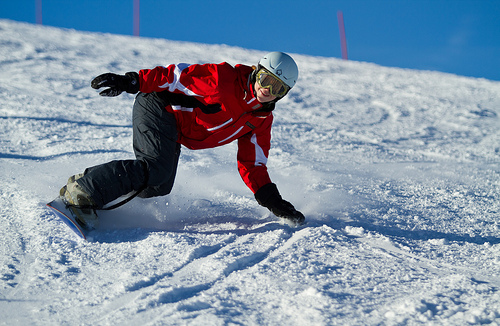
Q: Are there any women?
A: Yes, there is a woman.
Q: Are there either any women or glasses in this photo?
A: Yes, there is a woman.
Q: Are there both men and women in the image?
A: No, there is a woman but no men.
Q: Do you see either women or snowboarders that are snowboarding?
A: Yes, the woman is snowboarding.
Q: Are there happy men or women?
A: Yes, there is a happy woman.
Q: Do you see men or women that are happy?
A: Yes, the woman is happy.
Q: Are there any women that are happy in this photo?
A: Yes, there is a happy woman.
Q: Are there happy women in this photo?
A: Yes, there is a happy woman.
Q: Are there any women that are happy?
A: Yes, there is a woman that is happy.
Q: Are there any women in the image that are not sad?
A: Yes, there is a happy woman.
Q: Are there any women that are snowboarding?
A: Yes, there is a woman that is snowboarding.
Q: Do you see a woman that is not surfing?
A: Yes, there is a woman that is snowboarding .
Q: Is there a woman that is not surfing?
A: Yes, there is a woman that is snowboarding.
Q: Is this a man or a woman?
A: This is a woman.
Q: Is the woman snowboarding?
A: Yes, the woman is snowboarding.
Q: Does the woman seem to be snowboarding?
A: Yes, the woman is snowboarding.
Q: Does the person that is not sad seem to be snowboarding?
A: Yes, the woman is snowboarding.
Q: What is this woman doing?
A: The woman is snowboarding.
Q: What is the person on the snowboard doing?
A: The woman is snowboarding.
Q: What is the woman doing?
A: The woman is snowboarding.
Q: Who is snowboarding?
A: The woman is snowboarding.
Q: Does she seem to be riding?
A: No, the woman is snowboarding.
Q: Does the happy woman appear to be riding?
A: No, the woman is snowboarding.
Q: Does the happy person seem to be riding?
A: No, the woman is snowboarding.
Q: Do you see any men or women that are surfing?
A: No, there is a woman but she is snowboarding.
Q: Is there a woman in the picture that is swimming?
A: No, there is a woman but she is snowboarding.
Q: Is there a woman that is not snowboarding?
A: No, there is a woman but she is snowboarding.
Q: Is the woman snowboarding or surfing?
A: The woman is snowboarding.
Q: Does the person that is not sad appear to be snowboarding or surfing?
A: The woman is snowboarding.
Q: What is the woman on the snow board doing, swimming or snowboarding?
A: The woman is snowboarding.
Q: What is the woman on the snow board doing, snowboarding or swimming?
A: The woman is snowboarding.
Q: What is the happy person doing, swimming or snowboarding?
A: The woman is snowboarding.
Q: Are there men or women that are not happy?
A: No, there is a woman but she is happy.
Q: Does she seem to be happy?
A: Yes, the woman is happy.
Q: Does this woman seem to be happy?
A: Yes, the woman is happy.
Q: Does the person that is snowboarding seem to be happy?
A: Yes, the woman is happy.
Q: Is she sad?
A: No, the woman is happy.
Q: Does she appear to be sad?
A: No, the woman is happy.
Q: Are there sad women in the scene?
A: No, there is a woman but she is happy.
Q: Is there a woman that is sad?
A: No, there is a woman but she is happy.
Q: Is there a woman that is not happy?
A: No, there is a woman but she is happy.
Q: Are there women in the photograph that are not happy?
A: No, there is a woman but she is happy.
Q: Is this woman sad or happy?
A: The woman is happy.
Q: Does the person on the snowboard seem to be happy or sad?
A: The woman is happy.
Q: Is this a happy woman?
A: Yes, this is a happy woman.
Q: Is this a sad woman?
A: No, this is a happy woman.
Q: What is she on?
A: The woman is on the snowboard.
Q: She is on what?
A: The woman is on the snowboard.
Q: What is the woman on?
A: The woman is on the snowboard.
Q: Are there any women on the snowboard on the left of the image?
A: Yes, there is a woman on the snowboard.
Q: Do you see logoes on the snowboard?
A: No, there is a woman on the snowboard.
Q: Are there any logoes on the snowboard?
A: No, there is a woman on the snowboard.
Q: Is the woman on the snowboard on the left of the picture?
A: Yes, the woman is on the snowboard.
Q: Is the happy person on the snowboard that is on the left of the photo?
A: Yes, the woman is on the snowboard.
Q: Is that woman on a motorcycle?
A: No, the woman is on the snowboard.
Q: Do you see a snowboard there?
A: Yes, there is a snowboard.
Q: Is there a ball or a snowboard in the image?
A: Yes, there is a snowboard.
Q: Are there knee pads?
A: No, there are no knee pads.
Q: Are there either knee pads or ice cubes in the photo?
A: No, there are no knee pads or ice cubes.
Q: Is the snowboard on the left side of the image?
A: Yes, the snowboard is on the left of the image.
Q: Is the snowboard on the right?
A: No, the snowboard is on the left of the image.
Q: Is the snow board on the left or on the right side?
A: The snow board is on the left of the image.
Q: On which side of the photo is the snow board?
A: The snow board is on the left of the image.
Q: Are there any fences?
A: No, there are no fences.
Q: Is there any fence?
A: No, there are no fences.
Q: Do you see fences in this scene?
A: No, there are no fences.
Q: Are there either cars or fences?
A: No, there are no fences or cars.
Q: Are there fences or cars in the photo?
A: No, there are no fences or cars.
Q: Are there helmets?
A: Yes, there is a helmet.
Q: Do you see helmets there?
A: Yes, there is a helmet.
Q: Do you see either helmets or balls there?
A: Yes, there is a helmet.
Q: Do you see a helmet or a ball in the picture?
A: Yes, there is a helmet.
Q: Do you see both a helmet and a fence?
A: No, there is a helmet but no fences.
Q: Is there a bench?
A: No, there are no benches.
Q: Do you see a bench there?
A: No, there are no benches.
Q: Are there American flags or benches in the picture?
A: No, there are no benches or American flags.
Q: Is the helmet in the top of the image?
A: Yes, the helmet is in the top of the image.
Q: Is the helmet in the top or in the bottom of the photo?
A: The helmet is in the top of the image.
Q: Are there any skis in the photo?
A: No, there are no skis.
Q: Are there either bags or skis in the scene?
A: No, there are no skis or bags.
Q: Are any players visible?
A: No, there are no players.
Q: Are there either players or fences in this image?
A: No, there are no players or fences.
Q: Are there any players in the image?
A: No, there are no players.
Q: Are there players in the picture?
A: No, there are no players.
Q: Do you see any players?
A: No, there are no players.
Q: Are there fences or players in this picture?
A: No, there are no players or fences.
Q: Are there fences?
A: No, there are no fences.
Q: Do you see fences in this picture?
A: No, there are no fences.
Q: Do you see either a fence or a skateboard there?
A: No, there are no fences or skateboards.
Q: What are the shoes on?
A: The shoes are on the snowboard.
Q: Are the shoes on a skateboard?
A: No, the shoes are on the snowboard.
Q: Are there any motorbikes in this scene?
A: No, there are no motorbikes.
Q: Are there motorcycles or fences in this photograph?
A: No, there are no motorcycles or fences.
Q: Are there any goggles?
A: Yes, there are goggles.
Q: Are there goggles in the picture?
A: Yes, there are goggles.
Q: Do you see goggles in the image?
A: Yes, there are goggles.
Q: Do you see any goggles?
A: Yes, there are goggles.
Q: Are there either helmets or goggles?
A: Yes, there are goggles.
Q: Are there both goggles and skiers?
A: No, there are goggles but no skiers.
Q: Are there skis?
A: No, there are no skis.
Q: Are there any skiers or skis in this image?
A: No, there are no skis or skiers.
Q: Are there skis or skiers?
A: No, there are no skis or skiers.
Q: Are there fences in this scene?
A: No, there are no fences.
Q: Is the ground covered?
A: Yes, the ground is covered.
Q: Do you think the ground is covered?
A: Yes, the ground is covered.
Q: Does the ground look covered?
A: Yes, the ground is covered.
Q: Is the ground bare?
A: No, the ground is covered.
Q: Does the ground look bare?
A: No, the ground is covered.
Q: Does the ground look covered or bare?
A: The ground is covered.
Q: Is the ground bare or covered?
A: The ground is covered.